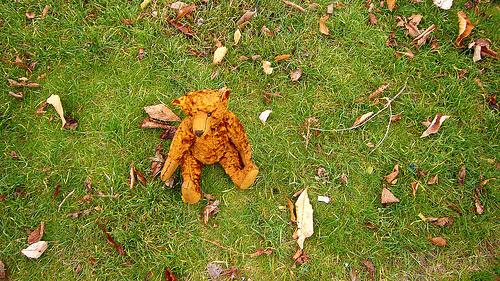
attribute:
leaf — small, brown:
[46, 85, 75, 121]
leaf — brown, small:
[209, 40, 232, 70]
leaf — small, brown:
[230, 9, 255, 31]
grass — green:
[8, 15, 480, 267]